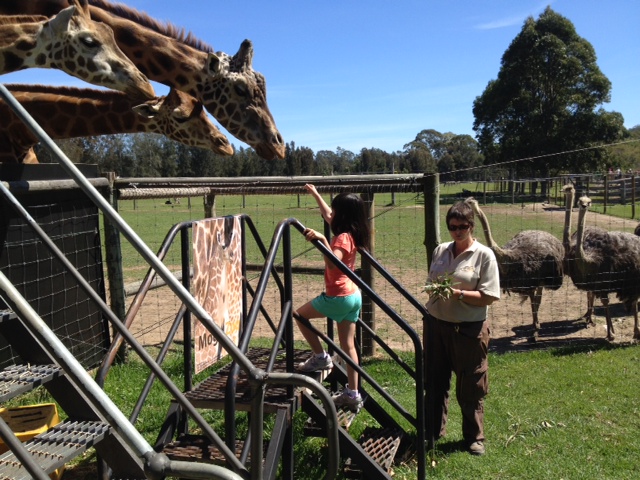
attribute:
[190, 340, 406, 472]
stairs — metal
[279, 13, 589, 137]
sky — blue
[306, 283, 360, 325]
shorts — green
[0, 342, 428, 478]
metal stairs — black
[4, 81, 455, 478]
railings — brown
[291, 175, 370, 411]
girl — young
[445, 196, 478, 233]
hair — short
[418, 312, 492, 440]
pants — brown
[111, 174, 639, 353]
fencing — around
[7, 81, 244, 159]
giraffe — reaching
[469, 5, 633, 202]
tree — large, green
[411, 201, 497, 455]
woman — brown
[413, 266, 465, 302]
food — green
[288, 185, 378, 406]
girl — young